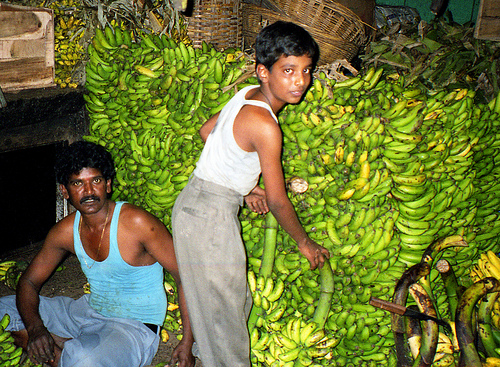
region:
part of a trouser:
[215, 293, 233, 328]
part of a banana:
[338, 310, 351, 326]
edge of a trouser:
[241, 313, 257, 334]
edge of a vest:
[115, 251, 142, 269]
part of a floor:
[154, 327, 175, 352]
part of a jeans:
[98, 328, 132, 361]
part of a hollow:
[9, 162, 56, 207]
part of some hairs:
[68, 126, 105, 183]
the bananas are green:
[376, 110, 440, 320]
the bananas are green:
[356, 150, 403, 313]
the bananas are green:
[330, 96, 387, 365]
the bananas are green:
[322, 157, 368, 348]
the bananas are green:
[397, 115, 417, 297]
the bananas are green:
[367, 176, 424, 363]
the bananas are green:
[347, 175, 386, 348]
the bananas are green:
[339, 160, 409, 363]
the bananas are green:
[311, 113, 347, 318]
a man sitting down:
[11, 130, 198, 359]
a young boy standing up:
[166, 17, 334, 362]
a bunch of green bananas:
[360, 100, 420, 140]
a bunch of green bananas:
[362, 135, 412, 170]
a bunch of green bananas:
[390, 165, 422, 201]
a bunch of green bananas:
[392, 195, 432, 231]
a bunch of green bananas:
[424, 90, 471, 125]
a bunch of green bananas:
[439, 120, 474, 167]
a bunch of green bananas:
[91, 27, 131, 59]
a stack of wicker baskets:
[246, 5, 368, 60]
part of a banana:
[301, 321, 313, 341]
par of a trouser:
[228, 287, 242, 307]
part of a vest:
[129, 283, 151, 305]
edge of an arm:
[182, 317, 189, 332]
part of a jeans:
[118, 330, 144, 353]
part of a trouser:
[203, 304, 231, 345]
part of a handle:
[369, 295, 404, 322]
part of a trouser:
[215, 292, 244, 330]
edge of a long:
[236, 308, 249, 331]